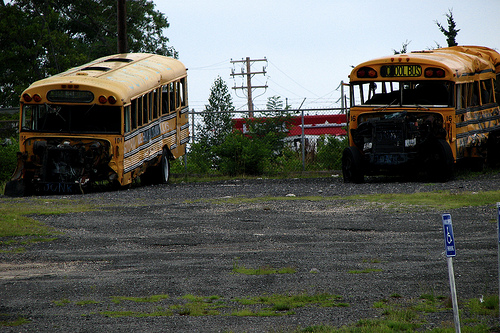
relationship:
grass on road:
[403, 185, 433, 215] [226, 199, 335, 274]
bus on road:
[342, 58, 454, 182] [226, 199, 335, 274]